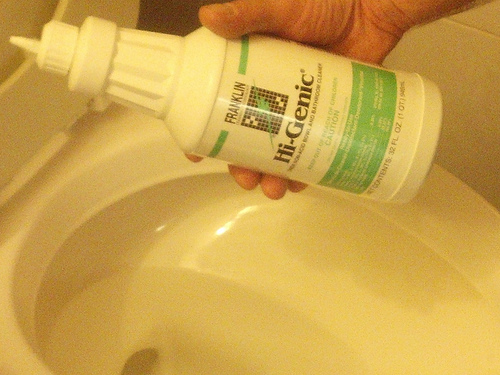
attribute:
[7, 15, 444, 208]
bottle — black, white, green, hi genic, 32 fl oz, fluted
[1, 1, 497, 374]
toilet — yellowish tint, white, edged, clean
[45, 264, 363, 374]
water — clear, clean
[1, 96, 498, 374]
toilet bowl — white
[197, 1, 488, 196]
hand — white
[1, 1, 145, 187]
toilet seat — put up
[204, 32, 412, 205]
label — green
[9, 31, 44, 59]
tip — pointy, closed, sharp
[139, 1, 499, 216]
wall — white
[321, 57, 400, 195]
block area — green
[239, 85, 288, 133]
grid — black